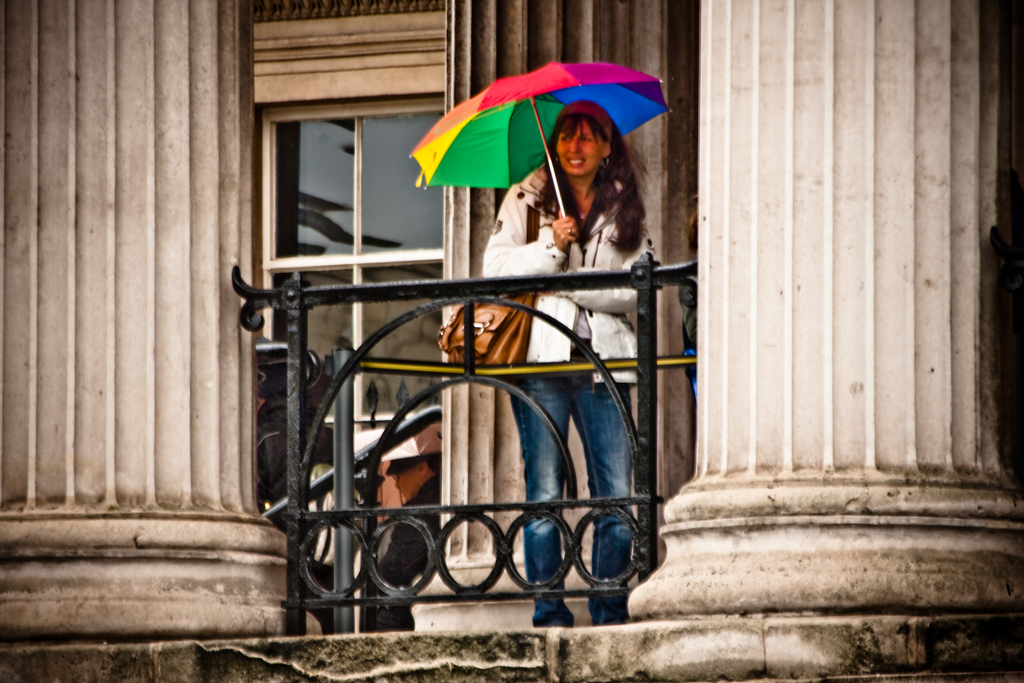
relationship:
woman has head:
[475, 94, 664, 632] [543, 89, 623, 202]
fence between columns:
[228, 243, 702, 630] [9, 3, 1021, 606]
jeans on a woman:
[511, 354, 653, 628] [475, 94, 664, 632]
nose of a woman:
[563, 128, 585, 157] [475, 94, 664, 632]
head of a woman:
[544, 96, 620, 196] [475, 94, 664, 632]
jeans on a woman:
[499, 333, 651, 621] [475, 94, 664, 632]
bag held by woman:
[436, 280, 539, 370] [438, 96, 668, 626]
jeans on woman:
[511, 354, 653, 628] [453, 117, 750, 625]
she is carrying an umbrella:
[476, 109, 662, 624] [404, 50, 672, 197]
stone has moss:
[904, 612, 987, 658] [916, 612, 992, 662]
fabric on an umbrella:
[405, 55, 674, 198] [404, 50, 672, 197]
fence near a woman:
[229, 243, 703, 630] [475, 94, 664, 632]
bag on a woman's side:
[435, 277, 539, 370] [461, 176, 561, 620]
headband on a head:
[549, 94, 623, 136] [549, 94, 617, 174]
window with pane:
[260, 85, 440, 427] [268, 100, 351, 261]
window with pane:
[260, 85, 440, 427] [357, 107, 440, 255]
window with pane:
[260, 85, 440, 427] [363, 262, 437, 433]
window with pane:
[260, 85, 440, 427] [275, 266, 356, 414]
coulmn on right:
[629, 18, 977, 613] [435, 14, 993, 652]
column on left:
[13, 27, 275, 626] [11, 16, 413, 675]